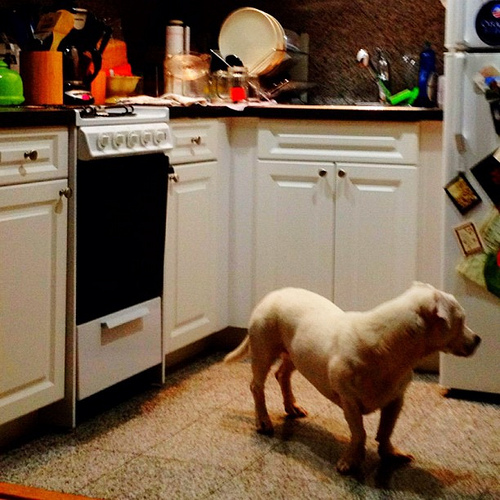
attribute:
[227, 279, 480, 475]
dog — beige, brown, white, small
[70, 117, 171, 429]
oven — black, white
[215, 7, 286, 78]
dishes — beige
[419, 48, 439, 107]
soap — blue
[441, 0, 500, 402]
refrigerator — white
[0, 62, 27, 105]
teapot — green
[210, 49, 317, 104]
strainer — silver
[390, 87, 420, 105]
sponge — green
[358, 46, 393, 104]
fixture — silver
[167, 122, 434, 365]
cabinets — white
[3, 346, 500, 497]
floor — tiled